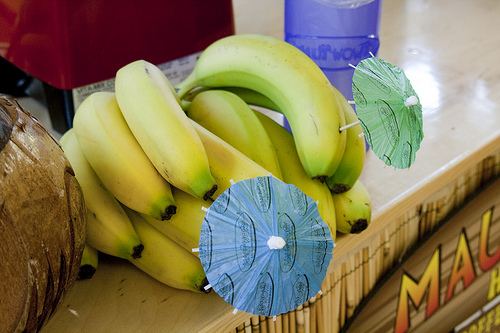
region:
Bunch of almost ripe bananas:
[55, 33, 372, 295]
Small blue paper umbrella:
[192, 173, 337, 321]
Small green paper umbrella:
[338, 51, 427, 168]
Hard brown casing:
[0, 93, 87, 332]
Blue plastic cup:
[282, 0, 378, 156]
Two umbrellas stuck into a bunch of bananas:
[53, 32, 424, 321]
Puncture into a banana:
[334, 119, 346, 138]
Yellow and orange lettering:
[394, 204, 497, 331]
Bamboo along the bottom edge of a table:
[219, 140, 497, 331]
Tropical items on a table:
[2, 1, 426, 331]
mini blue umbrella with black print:
[191, 174, 327, 314]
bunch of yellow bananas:
[58, 28, 373, 271]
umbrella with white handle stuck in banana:
[314, 45, 425, 169]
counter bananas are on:
[68, 0, 499, 330]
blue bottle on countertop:
[275, 7, 404, 136]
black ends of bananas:
[71, 170, 368, 303]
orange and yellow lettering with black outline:
[389, 206, 499, 331]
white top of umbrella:
[261, 234, 286, 251]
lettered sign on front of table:
[361, 189, 498, 328]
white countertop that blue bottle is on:
[12, 2, 495, 330]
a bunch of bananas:
[60, 23, 374, 285]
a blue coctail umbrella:
[185, 172, 345, 322]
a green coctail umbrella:
[332, 48, 429, 171]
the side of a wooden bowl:
[2, 85, 86, 331]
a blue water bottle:
[282, 3, 397, 119]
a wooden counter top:
[412, 26, 496, 133]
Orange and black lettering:
[377, 248, 474, 325]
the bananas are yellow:
[49, 33, 366, 213]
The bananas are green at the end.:
[74, 60, 265, 237]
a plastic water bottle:
[278, 4, 397, 71]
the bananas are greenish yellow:
[55, 18, 410, 308]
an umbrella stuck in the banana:
[315, 42, 430, 177]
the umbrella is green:
[314, 30, 464, 185]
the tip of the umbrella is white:
[389, 87, 422, 113]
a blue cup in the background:
[258, 3, 401, 97]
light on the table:
[383, 44, 482, 138]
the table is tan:
[407, 22, 487, 154]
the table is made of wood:
[395, 10, 488, 147]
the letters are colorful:
[384, 212, 499, 327]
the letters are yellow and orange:
[380, 217, 497, 319]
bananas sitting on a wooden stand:
[55, 29, 385, 299]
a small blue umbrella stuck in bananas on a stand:
[188, 170, 340, 322]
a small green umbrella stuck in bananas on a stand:
[332, 50, 429, 170]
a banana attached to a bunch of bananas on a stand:
[113, 58, 218, 196]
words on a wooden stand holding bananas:
[387, 203, 495, 332]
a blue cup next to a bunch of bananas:
[278, 0, 383, 107]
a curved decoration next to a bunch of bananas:
[0, 91, 87, 331]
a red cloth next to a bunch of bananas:
[0, 0, 242, 91]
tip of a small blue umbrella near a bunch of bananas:
[260, 230, 291, 257]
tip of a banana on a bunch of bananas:
[140, 188, 181, 227]